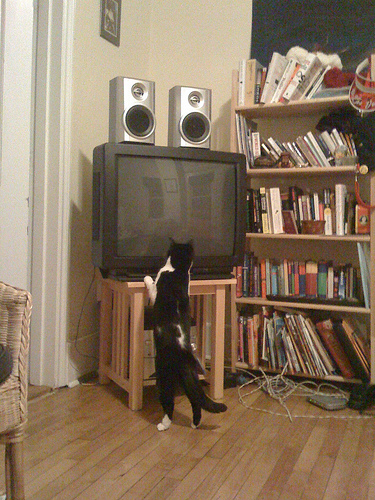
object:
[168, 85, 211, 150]
speakers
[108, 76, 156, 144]
speakers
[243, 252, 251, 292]
book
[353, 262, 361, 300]
books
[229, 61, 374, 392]
case shelf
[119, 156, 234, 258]
room reflection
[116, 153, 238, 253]
tv screen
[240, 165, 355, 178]
shelf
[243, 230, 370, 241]
shelf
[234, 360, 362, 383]
shelf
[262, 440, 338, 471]
ground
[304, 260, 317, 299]
book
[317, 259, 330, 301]
book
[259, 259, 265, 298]
book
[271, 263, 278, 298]
book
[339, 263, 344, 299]
book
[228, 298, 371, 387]
full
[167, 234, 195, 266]
head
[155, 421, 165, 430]
paw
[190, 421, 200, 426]
paw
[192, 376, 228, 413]
black tail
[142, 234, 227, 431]
cat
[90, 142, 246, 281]
television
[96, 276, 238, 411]
tv stand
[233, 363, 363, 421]
cords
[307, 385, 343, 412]
modem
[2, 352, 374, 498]
floor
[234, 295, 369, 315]
shelf